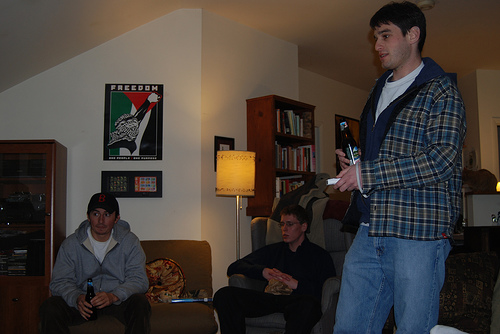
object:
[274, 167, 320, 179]
shelf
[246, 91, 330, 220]
book case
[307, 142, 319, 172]
book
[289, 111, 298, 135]
book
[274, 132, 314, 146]
shelf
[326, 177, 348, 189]
control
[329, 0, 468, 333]
man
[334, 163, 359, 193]
hand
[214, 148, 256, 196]
lamp shade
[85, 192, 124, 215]
cap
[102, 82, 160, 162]
art decor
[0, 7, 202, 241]
wall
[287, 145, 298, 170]
book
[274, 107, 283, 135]
book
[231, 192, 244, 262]
pole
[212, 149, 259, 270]
lamp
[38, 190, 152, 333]
man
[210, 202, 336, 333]
man